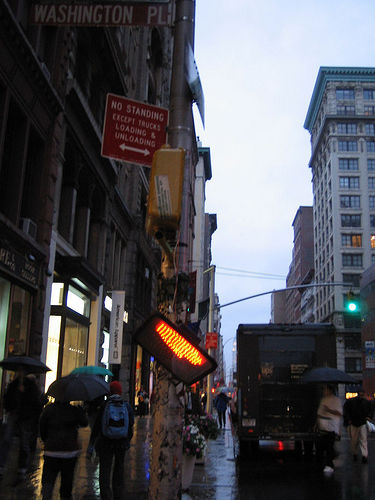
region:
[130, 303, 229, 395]
upside down crosswalk light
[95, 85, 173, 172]
red sign with white lettering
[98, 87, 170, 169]
sign indicating no standing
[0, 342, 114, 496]
group of people with umbrellas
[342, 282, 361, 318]
traffic control light with green light lit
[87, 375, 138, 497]
person wearing light blue backpack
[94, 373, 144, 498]
person wearing bright red hat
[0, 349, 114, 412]
two black umbrellas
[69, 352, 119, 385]
one green umbrella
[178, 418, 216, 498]
pot of flowers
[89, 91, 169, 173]
red and white sign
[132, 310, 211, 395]
orange lights lit up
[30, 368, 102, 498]
person carrying an umbrella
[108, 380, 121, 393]
red cap on the head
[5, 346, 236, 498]
people walking down the street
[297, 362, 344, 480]
person crossing the street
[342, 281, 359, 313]
traffic light flashing green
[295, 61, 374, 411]
tall tan building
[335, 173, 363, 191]
window with black lines on it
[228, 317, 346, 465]
large black vehicle on the road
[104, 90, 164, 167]
the red sign on the pole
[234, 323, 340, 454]
the truck on the road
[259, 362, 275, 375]
the "ups" on the truck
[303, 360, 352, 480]
the person walking behind the truck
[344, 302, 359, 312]
a green traffic light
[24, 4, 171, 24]
a sign that says "WASHINGTON PL"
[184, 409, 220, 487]
the potted flowers on the sidewalk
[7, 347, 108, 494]
the people on the sidewalk with umbrellas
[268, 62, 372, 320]
a group of tall buildings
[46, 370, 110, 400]
a dark colored opened umbrella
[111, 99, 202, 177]
red and white sign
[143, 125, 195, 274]
yellow pedestrian sign on pole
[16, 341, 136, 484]
people are holding umbrellas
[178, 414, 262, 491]
pavement near people is wet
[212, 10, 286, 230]
sky is grey and cloudy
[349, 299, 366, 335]
traffic light is green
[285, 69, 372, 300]
tall white and grey building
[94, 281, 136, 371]
black and white banner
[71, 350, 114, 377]
person holds green umbrella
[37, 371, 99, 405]
person holds blue umbrella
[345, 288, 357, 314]
A traffic light displaying a green light.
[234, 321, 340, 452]
A large dark colored van.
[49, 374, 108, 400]
A black umbrella.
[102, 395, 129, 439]
A light blue and black backpack.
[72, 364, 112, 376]
A green umbrella.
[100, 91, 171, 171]
A red and white street sign.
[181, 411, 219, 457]
White and pink flowers.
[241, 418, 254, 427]
A license plate on a vehicle.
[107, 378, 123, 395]
A red hat.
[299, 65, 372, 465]
A large beige building with windows.